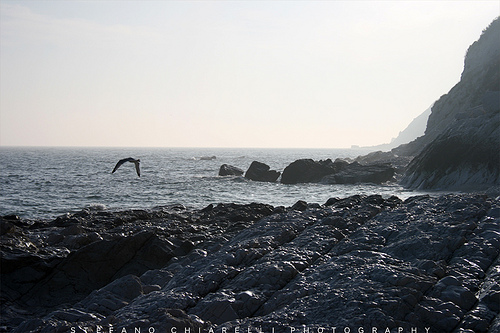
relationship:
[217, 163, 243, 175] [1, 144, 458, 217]
boulder in ocean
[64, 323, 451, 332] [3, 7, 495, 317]
photography studio took th shot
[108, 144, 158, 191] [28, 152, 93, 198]
bird flying over water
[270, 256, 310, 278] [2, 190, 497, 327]
crevices in rock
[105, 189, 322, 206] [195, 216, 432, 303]
crags in rocks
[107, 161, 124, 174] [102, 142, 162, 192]
wing of bird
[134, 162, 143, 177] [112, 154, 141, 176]
wing of bird